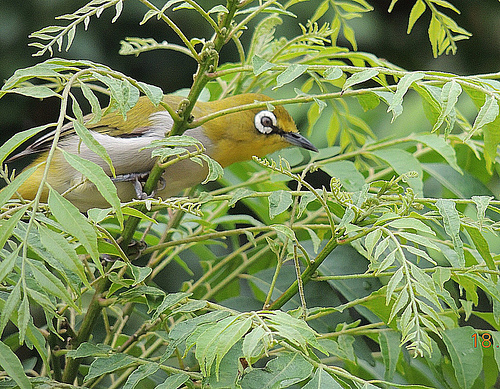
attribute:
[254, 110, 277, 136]
ring — white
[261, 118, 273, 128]
eye — black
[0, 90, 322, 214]
bird — yellow, white, perched, hiding, pretty, little, colored, attractive, sitting, beautiful, green, small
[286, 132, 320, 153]
beak — black, grey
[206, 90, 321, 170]
head — yellow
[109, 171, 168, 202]
talons — black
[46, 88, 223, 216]
body — white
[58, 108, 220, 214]
underside — white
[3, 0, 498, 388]
plants — green, leafy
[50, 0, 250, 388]
branch — green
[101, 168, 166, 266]
feet — black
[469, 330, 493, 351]
18 — number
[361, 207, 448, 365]
leaves — green, small